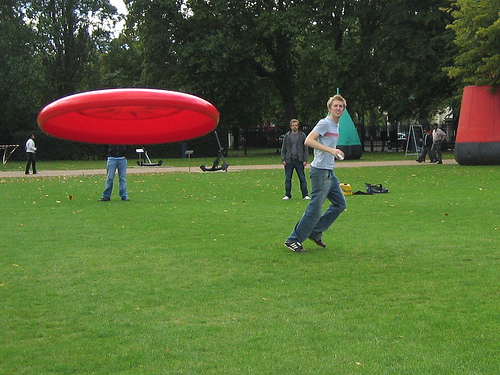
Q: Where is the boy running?
A: Grass.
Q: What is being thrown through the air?
A: Red frisbee.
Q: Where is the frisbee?
A: In the air in the foreground of the scene.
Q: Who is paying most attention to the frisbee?
A: Young man in light blue shirt.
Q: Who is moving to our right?
A: Young man in light blue shirt.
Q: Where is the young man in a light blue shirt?
A: On grass.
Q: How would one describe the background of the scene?
A: Group of trees.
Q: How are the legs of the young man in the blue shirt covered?
A: Jeans.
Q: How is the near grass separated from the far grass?
A: Sidewalk.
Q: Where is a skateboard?
A: On the sidewalk.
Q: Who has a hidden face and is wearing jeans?
A: Person behind frisbee in black shirt.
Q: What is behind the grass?
A: A long concrete sidewalk.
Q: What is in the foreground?
A: A frisbee.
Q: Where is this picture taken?
A: A park.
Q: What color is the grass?
A: Green.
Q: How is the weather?
A: Clear.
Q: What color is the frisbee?
A: Red.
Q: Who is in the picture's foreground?
A: A boy.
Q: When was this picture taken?
A: Daytime.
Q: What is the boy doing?
A: Throwing a frisbee.